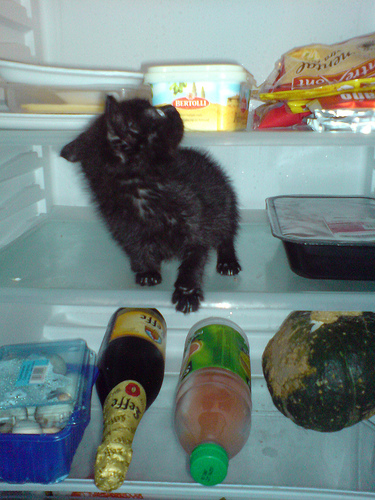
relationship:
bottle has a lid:
[98, 308, 164, 491] [188, 441, 227, 485]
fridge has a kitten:
[4, 1, 375, 499] [63, 96, 241, 285]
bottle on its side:
[98, 308, 164, 491] [150, 318, 164, 388]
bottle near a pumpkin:
[98, 308, 164, 491] [262, 307, 371, 431]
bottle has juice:
[98, 308, 164, 491] [115, 348, 135, 384]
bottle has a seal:
[98, 308, 164, 491] [93, 442, 134, 463]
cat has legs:
[63, 96, 241, 285] [136, 246, 240, 310]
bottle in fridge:
[98, 308, 164, 491] [4, 1, 375, 499]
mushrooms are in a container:
[1, 342, 65, 424] [0, 339, 96, 484]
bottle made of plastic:
[98, 308, 164, 491] [184, 390, 222, 430]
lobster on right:
[284, 200, 370, 238] [340, 198, 374, 242]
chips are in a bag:
[305, 88, 375, 134] [257, 37, 375, 125]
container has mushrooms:
[2, 64, 140, 119] [1, 342, 65, 424]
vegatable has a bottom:
[262, 307, 371, 431] [281, 406, 371, 435]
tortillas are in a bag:
[274, 38, 369, 87] [257, 37, 375, 125]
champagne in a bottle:
[93, 306, 168, 500] [98, 308, 164, 491]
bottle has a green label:
[182, 317, 252, 486] [184, 326, 251, 373]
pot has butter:
[146, 66, 253, 132] [177, 95, 218, 121]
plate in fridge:
[2, 114, 108, 126] [4, 1, 375, 499]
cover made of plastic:
[188, 441, 227, 485] [184, 390, 222, 430]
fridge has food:
[4, 1, 375, 499] [14, 103, 115, 115]